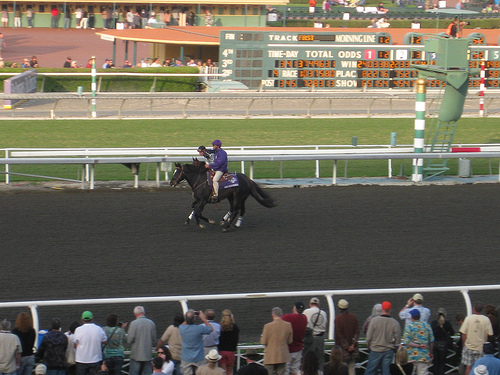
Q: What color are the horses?
A: Black.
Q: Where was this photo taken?
A: At a racetrack.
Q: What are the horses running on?
A: Dirt.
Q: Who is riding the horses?
A: Jockeys.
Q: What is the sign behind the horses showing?
A: Odds.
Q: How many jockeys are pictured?
A: Two.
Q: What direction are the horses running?
A: Left.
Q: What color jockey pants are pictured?
A: White.